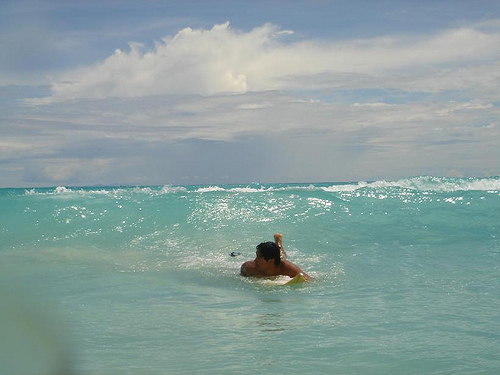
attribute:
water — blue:
[1, 174, 497, 372]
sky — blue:
[1, 3, 497, 186]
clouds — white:
[27, 19, 497, 187]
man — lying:
[239, 231, 310, 286]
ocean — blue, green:
[3, 177, 499, 374]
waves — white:
[4, 175, 498, 268]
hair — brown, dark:
[258, 240, 279, 260]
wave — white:
[3, 177, 499, 269]